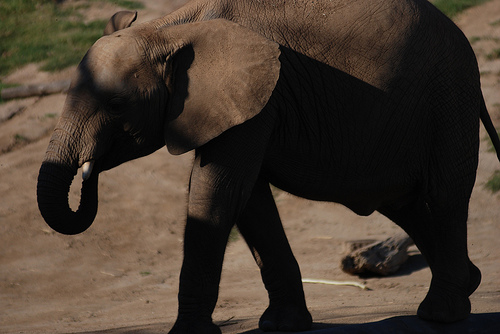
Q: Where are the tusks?
A: On either side of the trunk.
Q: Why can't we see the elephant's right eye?
A: Because it's turned to the left.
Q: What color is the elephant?
A: Grey.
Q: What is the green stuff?
A: Grass.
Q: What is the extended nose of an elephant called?
A: A trunk.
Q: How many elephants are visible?
A: One.